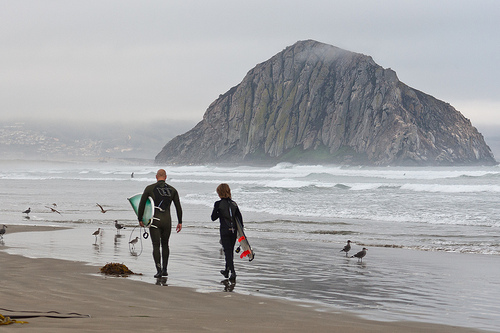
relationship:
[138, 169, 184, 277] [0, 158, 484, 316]
man walking down beach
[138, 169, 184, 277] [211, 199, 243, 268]
man wearing wetsuit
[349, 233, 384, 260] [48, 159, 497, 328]
bird standing on beach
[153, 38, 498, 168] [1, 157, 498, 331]
rock sticking out water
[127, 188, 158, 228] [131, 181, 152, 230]
surboard under arm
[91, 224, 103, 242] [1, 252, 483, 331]
bird on beach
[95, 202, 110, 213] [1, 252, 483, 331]
bird on beach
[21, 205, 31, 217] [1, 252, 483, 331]
bird on beach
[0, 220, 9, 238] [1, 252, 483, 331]
bird on beach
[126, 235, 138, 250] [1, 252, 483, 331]
bird on beach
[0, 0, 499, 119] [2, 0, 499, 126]
fog in sky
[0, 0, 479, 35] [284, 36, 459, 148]
fog over rock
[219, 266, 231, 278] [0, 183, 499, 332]
foot lifted off beach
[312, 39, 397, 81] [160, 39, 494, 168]
edge of a mountain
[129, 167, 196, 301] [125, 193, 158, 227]
man carrying a surfboard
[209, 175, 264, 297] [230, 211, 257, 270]
man carrying a surfboard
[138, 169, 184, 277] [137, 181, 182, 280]
man wearing wetsuit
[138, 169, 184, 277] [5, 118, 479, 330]
man walking on shore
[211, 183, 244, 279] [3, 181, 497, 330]
man walking on shore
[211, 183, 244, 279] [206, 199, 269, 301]
man wearing wetsuit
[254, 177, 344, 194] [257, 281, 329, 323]
waves reaching shore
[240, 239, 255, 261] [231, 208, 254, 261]
part of surfboard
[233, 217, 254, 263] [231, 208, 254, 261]
part of surfboard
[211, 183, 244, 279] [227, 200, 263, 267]
man clutching surfboard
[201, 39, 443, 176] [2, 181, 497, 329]
mountain on beach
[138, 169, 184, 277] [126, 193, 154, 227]
man clutching surboard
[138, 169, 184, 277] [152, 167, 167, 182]
man with bald head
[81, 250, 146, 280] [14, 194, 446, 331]
weed on beach